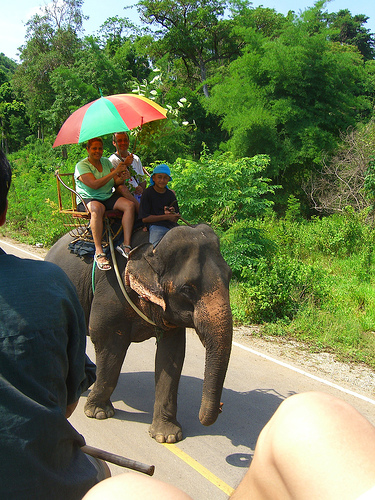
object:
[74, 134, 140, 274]
person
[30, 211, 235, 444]
elephant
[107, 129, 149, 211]
person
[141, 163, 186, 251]
person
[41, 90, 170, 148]
umbrella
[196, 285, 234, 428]
trunk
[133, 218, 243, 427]
head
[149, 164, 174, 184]
cap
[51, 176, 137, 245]
bench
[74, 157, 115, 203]
t-shirt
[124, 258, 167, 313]
ear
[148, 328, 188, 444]
front legs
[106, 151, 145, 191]
shirt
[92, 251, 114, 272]
sandal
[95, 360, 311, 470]
shadow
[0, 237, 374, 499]
ground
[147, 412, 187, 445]
foot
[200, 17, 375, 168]
tree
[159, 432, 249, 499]
line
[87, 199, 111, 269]
leg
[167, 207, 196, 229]
stick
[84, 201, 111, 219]
knee